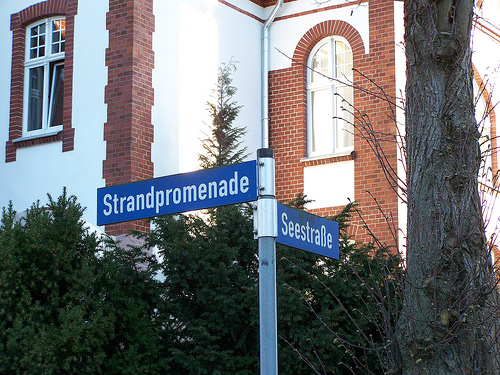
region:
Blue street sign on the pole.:
[189, 189, 201, 204]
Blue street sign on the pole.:
[220, 189, 244, 196]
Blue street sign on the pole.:
[280, 194, 341, 256]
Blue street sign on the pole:
[90, 161, 257, 213]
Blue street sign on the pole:
[278, 198, 350, 263]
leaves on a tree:
[47, 233, 222, 342]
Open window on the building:
[15, 15, 67, 139]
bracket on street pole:
[249, 148, 278, 252]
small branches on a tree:
[363, 79, 462, 361]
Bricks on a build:
[103, 20, 161, 220]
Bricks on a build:
[353, 84, 393, 201]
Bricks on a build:
[10, 25, 23, 131]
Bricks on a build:
[268, 71, 297, 181]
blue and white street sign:
[82, 154, 266, 226]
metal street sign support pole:
[241, 140, 295, 374]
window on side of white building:
[3, 13, 90, 166]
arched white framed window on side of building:
[294, 33, 361, 164]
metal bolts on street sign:
[247, 203, 267, 237]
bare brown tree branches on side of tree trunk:
[316, 66, 428, 214]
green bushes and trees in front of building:
[2, 57, 365, 372]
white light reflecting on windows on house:
[303, 43, 350, 159]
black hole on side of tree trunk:
[435, 7, 470, 42]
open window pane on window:
[43, 60, 78, 139]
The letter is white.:
[101, 188, 113, 219]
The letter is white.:
[110, 187, 120, 219]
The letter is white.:
[118, 189, 128, 219]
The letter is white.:
[123, 190, 136, 215]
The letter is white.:
[132, 183, 147, 215]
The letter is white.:
[142, 180, 156, 210]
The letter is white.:
[153, 185, 166, 215]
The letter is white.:
[162, 183, 174, 208]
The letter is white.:
[170, 183, 182, 208]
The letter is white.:
[179, 179, 199, 206]